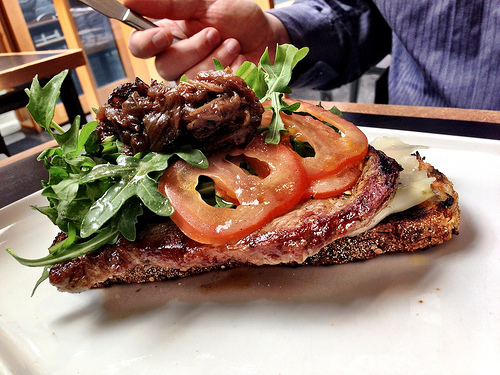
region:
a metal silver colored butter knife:
[78, 0, 181, 41]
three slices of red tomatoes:
[158, 88, 371, 245]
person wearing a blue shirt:
[124, 2, 499, 109]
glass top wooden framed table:
[1, 46, 82, 156]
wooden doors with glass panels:
[1, 0, 161, 132]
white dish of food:
[5, 124, 495, 374]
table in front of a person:
[2, 98, 499, 218]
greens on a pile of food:
[23, 37, 459, 293]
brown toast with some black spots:
[51, 149, 458, 291]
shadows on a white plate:
[47, 207, 490, 344]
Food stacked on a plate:
[22, 41, 497, 278]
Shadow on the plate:
[89, 260, 386, 327]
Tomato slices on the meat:
[165, 131, 332, 232]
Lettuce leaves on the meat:
[45, 110, 129, 228]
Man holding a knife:
[94, 8, 221, 72]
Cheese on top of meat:
[370, 124, 453, 244]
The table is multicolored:
[392, 102, 487, 139]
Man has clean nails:
[139, 21, 269, 71]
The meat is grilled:
[75, 90, 452, 277]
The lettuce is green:
[59, 145, 159, 225]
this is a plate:
[171, 318, 249, 345]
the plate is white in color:
[213, 319, 288, 372]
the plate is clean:
[186, 310, 271, 348]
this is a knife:
[81, 0, 185, 40]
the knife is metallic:
[79, 2, 141, 24]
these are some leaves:
[52, 115, 132, 220]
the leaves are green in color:
[79, 146, 109, 224]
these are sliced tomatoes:
[203, 149, 315, 201]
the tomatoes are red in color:
[201, 216, 229, 226]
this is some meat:
[391, 201, 447, 236]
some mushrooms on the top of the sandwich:
[98, 75, 258, 146]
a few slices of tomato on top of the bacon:
[172, 117, 363, 229]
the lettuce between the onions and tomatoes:
[26, 49, 315, 233]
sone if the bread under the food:
[331, 211, 469, 271]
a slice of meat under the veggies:
[36, 198, 406, 285]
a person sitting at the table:
[126, 4, 498, 124]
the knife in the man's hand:
[88, 1, 160, 33]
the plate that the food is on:
[1, 138, 497, 370]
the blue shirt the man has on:
[272, 2, 497, 91]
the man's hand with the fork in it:
[113, 2, 293, 74]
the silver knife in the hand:
[72, 0, 177, 49]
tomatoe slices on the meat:
[177, 106, 355, 213]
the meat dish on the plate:
[8, 44, 431, 371]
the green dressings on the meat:
[5, 64, 94, 283]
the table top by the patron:
[0, 39, 85, 89]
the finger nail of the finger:
[150, 26, 171, 48]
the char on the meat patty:
[313, 156, 397, 241]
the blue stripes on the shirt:
[382, 0, 485, 100]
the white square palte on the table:
[0, 177, 43, 369]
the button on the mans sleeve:
[312, 66, 326, 83]